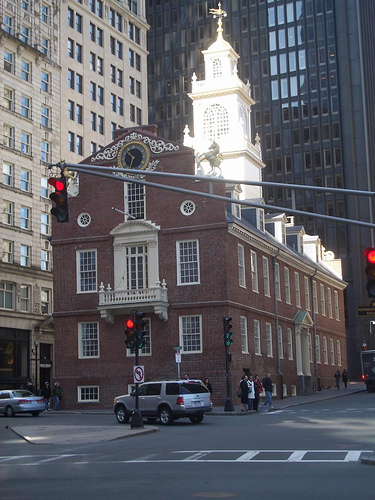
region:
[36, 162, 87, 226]
Red traffic signal in the air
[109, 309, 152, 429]
Red traffic signal on a corner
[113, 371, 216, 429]
Silver SUV on a road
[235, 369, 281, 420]
People standing on a corner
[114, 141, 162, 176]
Clock on a building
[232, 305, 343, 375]
Windows on a building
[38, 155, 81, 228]
a red light on a pole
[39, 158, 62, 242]
a red light on a metal pole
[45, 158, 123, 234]
a traffic light on a pole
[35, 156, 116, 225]
a traffic light on a metal pole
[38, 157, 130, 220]
a metal pole with a traffic light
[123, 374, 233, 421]
vehicle on the road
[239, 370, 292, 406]
people on the sidewalk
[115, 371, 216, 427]
This is a car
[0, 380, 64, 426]
This is a car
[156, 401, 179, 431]
Wheel of a car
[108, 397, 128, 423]
Wheel of a car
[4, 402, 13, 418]
Wheel of a car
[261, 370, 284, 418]
This is a person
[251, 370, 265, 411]
This is a person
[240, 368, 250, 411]
This is a person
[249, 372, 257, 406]
This is a person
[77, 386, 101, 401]
glass window on building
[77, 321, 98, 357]
glass window on building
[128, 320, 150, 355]
glass window on building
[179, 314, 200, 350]
glass window on building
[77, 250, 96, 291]
glass window on building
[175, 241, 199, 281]
glass window on building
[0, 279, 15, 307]
glass window on building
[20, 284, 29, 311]
glass window on building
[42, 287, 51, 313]
glass window on building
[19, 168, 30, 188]
glass window on building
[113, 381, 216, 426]
Silver Sports utility vehicle driving on the street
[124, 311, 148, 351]
Traffic light displaying red color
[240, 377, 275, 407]
Crowd of people waiting to cross the street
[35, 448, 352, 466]
Crosswalk in the street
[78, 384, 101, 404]
A window at the base of a structure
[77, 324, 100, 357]
A window near the top of a structure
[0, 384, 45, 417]
A silver car driving in the street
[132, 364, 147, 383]
A sign displaying a no left turn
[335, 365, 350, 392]
Two people walking on the sidewalk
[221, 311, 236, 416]
Traffic signal displaying green lights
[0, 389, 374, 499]
an asphalt city street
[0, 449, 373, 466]
a white crosswalk in the street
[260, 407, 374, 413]
a white crosswalk in the street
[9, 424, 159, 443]
a concrete island in the street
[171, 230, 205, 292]
A window on a building.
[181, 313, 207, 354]
A window on a building.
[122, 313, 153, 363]
A window on a building.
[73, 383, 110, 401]
A window on a building.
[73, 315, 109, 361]
A window on a building.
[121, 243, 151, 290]
A window on a building.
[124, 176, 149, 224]
A window on a building.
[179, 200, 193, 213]
A window on a building.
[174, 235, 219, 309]
A window on a building.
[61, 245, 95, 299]
A window on a building.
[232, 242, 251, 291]
A window on a building.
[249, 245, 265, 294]
A window on a building.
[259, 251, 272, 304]
A window on a building.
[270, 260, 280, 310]
A window on a building.